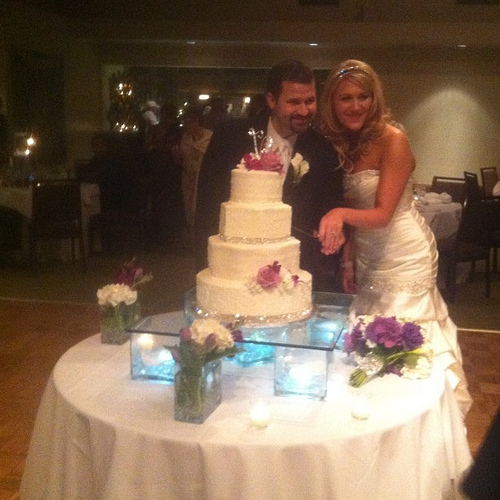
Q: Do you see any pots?
A: No, there are no pots.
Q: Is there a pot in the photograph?
A: No, there are no pots.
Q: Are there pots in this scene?
A: No, there are no pots.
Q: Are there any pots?
A: No, there are no pots.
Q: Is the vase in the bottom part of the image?
A: Yes, the vase is in the bottom of the image.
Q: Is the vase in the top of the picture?
A: No, the vase is in the bottom of the image.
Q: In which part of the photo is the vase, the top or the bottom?
A: The vase is in the bottom of the image.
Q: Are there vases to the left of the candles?
A: Yes, there is a vase to the left of the candles.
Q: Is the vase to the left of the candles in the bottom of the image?
A: Yes, the vase is to the left of the candles.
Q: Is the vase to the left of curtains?
A: No, the vase is to the left of the candles.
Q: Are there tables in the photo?
A: Yes, there is a table.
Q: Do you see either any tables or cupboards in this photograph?
A: Yes, there is a table.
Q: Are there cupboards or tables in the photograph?
A: Yes, there is a table.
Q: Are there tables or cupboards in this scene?
A: Yes, there is a table.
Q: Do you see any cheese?
A: No, there is no cheese.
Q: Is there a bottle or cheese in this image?
A: No, there are no cheese or bottles.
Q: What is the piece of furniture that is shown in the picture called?
A: The piece of furniture is a table.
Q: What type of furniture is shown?
A: The furniture is a table.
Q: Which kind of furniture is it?
A: The piece of furniture is a table.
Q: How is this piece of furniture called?
A: This is a table.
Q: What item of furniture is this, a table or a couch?
A: This is a table.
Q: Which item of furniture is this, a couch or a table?
A: This is a table.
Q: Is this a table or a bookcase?
A: This is a table.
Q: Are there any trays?
A: No, there are no trays.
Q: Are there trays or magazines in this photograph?
A: No, there are no trays or magazines.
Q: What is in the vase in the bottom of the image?
A: The flowers are in the vase.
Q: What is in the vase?
A: The flowers are in the vase.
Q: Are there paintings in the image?
A: No, there are no paintings.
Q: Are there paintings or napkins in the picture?
A: No, there are no paintings or napkins.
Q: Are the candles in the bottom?
A: Yes, the candles are in the bottom of the image.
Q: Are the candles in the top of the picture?
A: No, the candles are in the bottom of the image.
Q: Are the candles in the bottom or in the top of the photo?
A: The candles are in the bottom of the image.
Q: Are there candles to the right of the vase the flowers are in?
A: Yes, there are candles to the right of the vase.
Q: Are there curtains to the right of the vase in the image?
A: No, there are candles to the right of the vase.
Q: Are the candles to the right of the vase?
A: Yes, the candles are to the right of the vase.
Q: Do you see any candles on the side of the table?
A: Yes, there are candles on the side of the table.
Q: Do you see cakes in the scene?
A: Yes, there is a cake.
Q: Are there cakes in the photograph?
A: Yes, there is a cake.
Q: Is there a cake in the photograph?
A: Yes, there is a cake.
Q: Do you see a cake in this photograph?
A: Yes, there is a cake.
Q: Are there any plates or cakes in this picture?
A: Yes, there is a cake.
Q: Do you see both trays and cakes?
A: No, there is a cake but no trays.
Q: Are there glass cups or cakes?
A: Yes, there is a glass cake.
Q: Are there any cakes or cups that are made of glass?
A: Yes, the cake is made of glass.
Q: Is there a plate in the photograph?
A: No, there are no plates.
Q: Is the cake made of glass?
A: Yes, the cake is made of glass.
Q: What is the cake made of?
A: The cake is made of glass.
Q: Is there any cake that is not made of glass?
A: No, there is a cake but it is made of glass.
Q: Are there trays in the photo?
A: No, there are no trays.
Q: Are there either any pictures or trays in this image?
A: No, there are no trays or pictures.